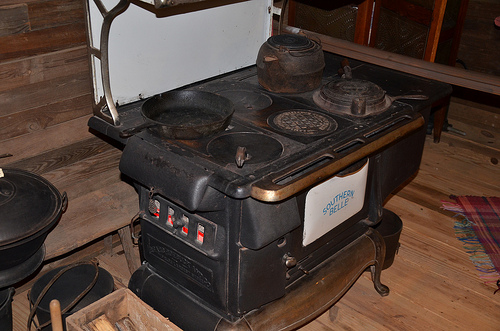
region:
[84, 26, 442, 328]
black wood burning stove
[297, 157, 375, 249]
"Southern Belle" written on the stove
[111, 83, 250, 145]
cast iron frying pan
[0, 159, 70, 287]
large cast iron pot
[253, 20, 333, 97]
rusty cast iron kettle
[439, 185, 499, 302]
plaid throw rug with fringe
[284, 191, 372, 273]
door of the stove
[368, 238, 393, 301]
foot of the stove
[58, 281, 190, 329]
container of fire wood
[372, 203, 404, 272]
metal pot on the floor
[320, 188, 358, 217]
Words in blue: Southern Belle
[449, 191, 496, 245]
Red and blue plaid rug on the floor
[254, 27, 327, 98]
Cast iron kettle on the stove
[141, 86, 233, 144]
Cast iron skillet on old timey stove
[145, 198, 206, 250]
Vent for the antique fire burning stove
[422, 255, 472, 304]
Hardwood floor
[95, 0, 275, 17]
Rack above the stove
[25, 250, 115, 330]
Rusty old metal tongs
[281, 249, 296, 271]
Brass knob on the front of the stove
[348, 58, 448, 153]
Short wooden table in the background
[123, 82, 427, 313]
black stove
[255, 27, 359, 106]
black kettle on stove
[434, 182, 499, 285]
fringe on plaid rug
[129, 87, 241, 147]
cast iron skillet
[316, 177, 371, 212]
blue writting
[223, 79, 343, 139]
middle burners on stove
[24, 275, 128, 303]
black bucket on floor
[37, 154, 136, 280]
brown bench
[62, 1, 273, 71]
white screen behind stove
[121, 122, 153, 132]
handle on black pan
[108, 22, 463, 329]
old slightly rusty cast iron stove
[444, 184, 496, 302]
fringe edged rug on floor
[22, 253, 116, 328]
metal tongs resting on cast iron pot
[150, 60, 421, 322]
Southern Belle brand cast iron stove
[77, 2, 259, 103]
white heat protective backing on wall in back of stove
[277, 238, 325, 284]
damper control on wood stove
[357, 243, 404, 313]
claw type feet on wood stove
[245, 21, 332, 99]
cast iron tea kettle on wood stove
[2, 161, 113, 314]
cast iron pots at side of stove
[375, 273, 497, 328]
wood type flooring beneath wood stove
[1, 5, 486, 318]
The stove was made a long time ago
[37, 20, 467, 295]
The stove is made of cast iron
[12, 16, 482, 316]
The stove needs wood to function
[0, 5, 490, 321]
The stove burns wood for cooking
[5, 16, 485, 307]
The stove is a nice antique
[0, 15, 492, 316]
A nice antique is on display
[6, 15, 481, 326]
An antique stove is in the room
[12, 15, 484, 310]
The antique stove is being sold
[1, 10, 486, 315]
The antique stove is very expensive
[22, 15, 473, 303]
The antique stove is complete with pots